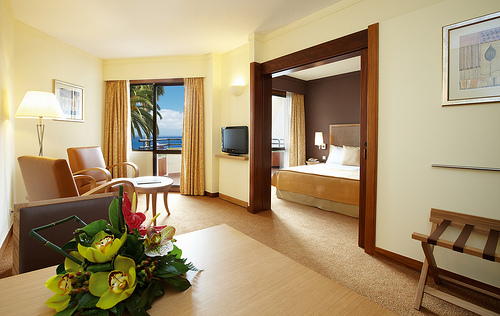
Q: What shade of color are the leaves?
A: Green.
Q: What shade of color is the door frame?
A: Brown.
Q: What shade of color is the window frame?
A: Black.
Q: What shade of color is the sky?
A: Blue.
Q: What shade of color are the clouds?
A: White.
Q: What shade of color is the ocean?
A: Blue.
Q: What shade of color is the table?
A: Brown.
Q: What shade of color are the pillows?
A: White.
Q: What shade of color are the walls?
A: Cream.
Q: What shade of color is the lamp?
A: White.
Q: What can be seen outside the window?
A: Palm tree and clouds.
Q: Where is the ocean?
A: Outside the window.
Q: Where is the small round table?
A: In front of the chairs.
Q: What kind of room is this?
A: A hotel room.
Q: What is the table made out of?
A: Wood.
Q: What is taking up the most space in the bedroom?
A: Large bed.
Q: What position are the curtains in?
A: Open.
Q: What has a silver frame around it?
A: Picture on the wall.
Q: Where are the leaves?
A: On the plant.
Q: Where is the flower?
A: On floor.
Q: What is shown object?
A: Flower.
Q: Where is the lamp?
A: Behind chairs.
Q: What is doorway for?
A: Bedroom.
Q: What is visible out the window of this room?
A: The ocean.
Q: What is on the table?
A: Flowers.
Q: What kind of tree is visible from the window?
A: A palm tree.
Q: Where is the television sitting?
A: On a ledge on the wall.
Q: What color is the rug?
A: Gold.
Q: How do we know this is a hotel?
A: The luggage rack.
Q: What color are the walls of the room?
A: Yellow.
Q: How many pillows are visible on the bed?
A: Two.